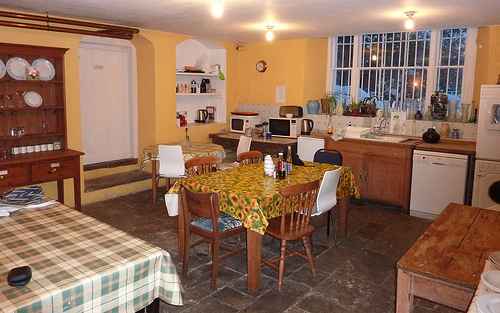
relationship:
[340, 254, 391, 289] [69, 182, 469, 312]
tile on floor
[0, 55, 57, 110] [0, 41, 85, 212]
utensils on cabinet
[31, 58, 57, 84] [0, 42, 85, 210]
plate on shelf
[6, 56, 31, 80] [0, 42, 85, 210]
plate on shelf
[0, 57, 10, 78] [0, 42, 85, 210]
plate on shelf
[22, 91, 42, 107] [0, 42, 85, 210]
plate on shelf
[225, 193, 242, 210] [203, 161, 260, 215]
flower on table cloth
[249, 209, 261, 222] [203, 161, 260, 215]
flower on table cloth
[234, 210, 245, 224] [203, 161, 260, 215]
flower on table cloth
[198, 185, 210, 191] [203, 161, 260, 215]
flower on table cloth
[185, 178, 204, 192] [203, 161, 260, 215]
flower on table cloth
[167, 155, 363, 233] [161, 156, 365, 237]
sunflowers on tablecloth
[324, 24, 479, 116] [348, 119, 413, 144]
window above sink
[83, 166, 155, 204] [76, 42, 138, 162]
step leading up to door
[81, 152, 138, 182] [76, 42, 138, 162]
step leading up to door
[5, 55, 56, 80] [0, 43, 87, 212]
china displayed in cabinet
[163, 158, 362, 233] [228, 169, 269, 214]
cloth has flowers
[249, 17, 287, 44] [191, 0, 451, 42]
lights on ceiling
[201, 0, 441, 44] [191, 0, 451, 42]
lights on ceiling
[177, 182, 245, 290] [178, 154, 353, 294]
chair around table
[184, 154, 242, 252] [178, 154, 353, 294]
chair around table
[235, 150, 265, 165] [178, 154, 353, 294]
chair around table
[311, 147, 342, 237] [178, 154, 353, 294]
chair around table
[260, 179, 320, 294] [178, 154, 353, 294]
chair around table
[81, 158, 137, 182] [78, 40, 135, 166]
step in front of door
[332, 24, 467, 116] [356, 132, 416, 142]
window above sink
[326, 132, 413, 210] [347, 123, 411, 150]
cabinet below sink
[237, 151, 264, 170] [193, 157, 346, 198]
chair around table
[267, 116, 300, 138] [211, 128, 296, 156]
microwave on table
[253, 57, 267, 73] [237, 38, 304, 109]
clock hanging on wall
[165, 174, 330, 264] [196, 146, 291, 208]
table with tablecloth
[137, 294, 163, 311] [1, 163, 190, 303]
table with tablecloth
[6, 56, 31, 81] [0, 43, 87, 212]
plate in a cabinet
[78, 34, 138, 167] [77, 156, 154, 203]
door has step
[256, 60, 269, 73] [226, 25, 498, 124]
clock on wall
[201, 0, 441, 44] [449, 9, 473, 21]
lights are on ceiling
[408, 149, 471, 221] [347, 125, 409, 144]
dishwasher near sink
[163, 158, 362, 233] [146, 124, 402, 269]
cloth on table